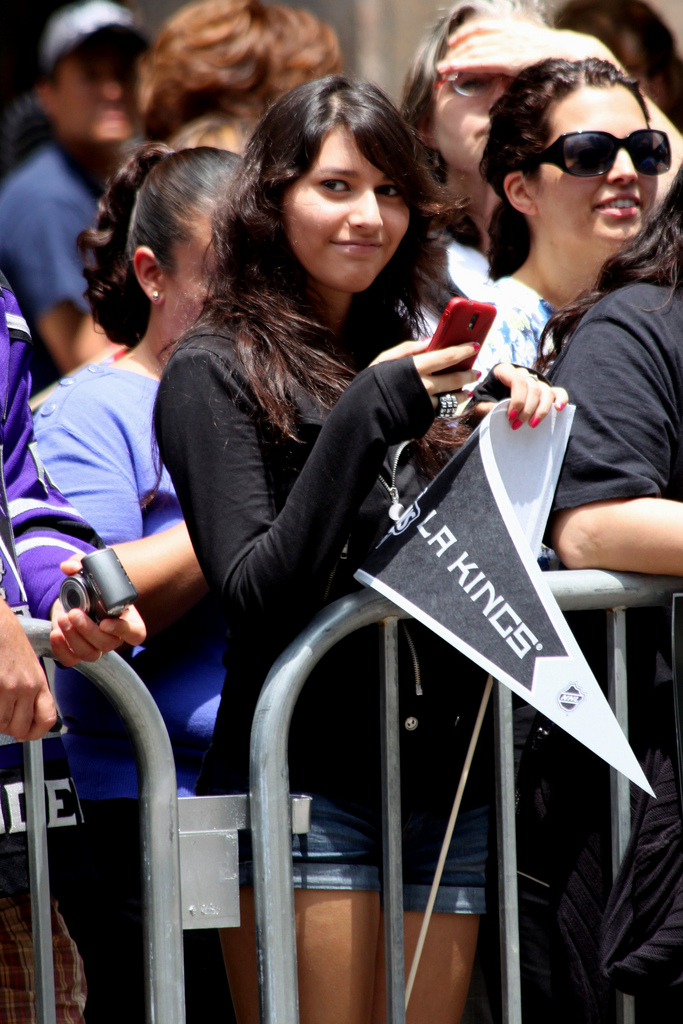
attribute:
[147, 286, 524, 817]
shirt — black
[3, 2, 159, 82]
hat — blue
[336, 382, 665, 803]
flag — black and white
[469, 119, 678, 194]
sunglasses — black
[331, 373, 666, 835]
banner — black and white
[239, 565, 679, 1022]
barricade — metal